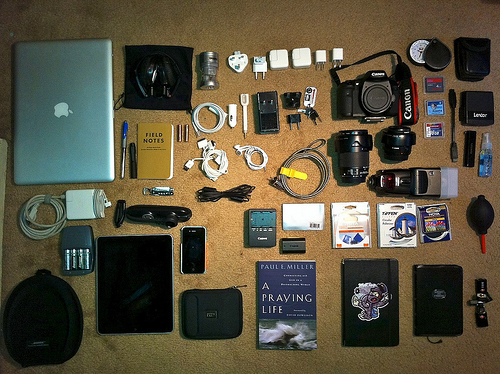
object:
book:
[255, 257, 318, 351]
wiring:
[262, 137, 329, 197]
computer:
[13, 37, 116, 185]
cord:
[195, 184, 255, 203]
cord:
[190, 101, 228, 135]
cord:
[182, 137, 229, 182]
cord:
[18, 193, 66, 242]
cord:
[92, 188, 111, 219]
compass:
[406, 38, 452, 70]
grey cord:
[270, 138, 331, 201]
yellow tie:
[280, 167, 308, 180]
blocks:
[268, 47, 345, 71]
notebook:
[137, 122, 174, 179]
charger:
[61, 224, 96, 275]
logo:
[54, 102, 74, 118]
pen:
[120, 120, 130, 179]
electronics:
[5, 26, 499, 371]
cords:
[191, 101, 228, 134]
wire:
[192, 93, 250, 141]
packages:
[331, 202, 451, 248]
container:
[59, 225, 95, 277]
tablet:
[94, 234, 174, 335]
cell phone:
[180, 226, 206, 274]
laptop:
[10, 36, 115, 185]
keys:
[304, 107, 323, 125]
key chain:
[304, 86, 318, 106]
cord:
[267, 137, 335, 199]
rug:
[8, 20, 495, 370]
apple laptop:
[10, 37, 114, 185]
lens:
[334, 128, 374, 185]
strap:
[327, 49, 402, 83]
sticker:
[351, 282, 394, 322]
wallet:
[341, 256, 401, 346]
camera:
[337, 69, 397, 125]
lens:
[381, 125, 417, 160]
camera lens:
[334, 130, 373, 183]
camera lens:
[381, 126, 417, 161]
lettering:
[403, 88, 413, 119]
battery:
[70, 249, 79, 270]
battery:
[77, 249, 86, 270]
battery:
[84, 248, 91, 269]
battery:
[64, 249, 73, 271]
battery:
[70, 249, 78, 270]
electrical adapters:
[226, 47, 344, 81]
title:
[255, 280, 315, 319]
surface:
[0, 1, 499, 373]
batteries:
[64, 248, 90, 271]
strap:
[279, 167, 307, 181]